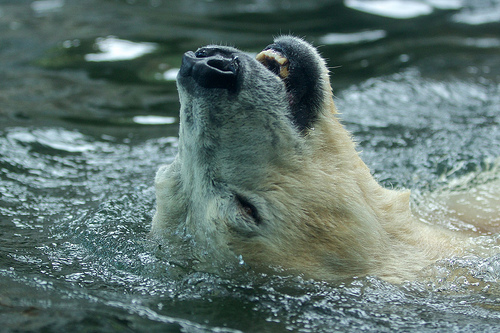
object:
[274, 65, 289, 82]
tooth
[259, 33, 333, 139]
bottom jaw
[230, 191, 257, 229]
eye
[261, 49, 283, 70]
tooth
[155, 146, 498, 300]
fur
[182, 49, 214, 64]
nostril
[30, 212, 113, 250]
water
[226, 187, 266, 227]
right eye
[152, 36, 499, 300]
polar bear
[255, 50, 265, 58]
tooth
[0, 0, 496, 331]
water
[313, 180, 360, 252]
fur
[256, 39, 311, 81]
teeth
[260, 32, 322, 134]
lips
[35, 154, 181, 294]
water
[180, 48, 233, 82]
nostril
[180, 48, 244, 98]
nose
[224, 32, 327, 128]
mouth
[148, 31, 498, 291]
bear